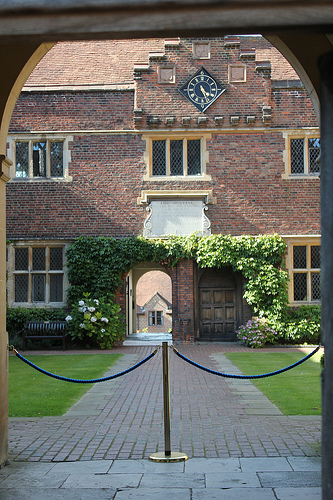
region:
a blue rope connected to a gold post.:
[8, 341, 169, 383]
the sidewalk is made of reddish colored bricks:
[193, 405, 290, 453]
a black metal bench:
[20, 321, 67, 351]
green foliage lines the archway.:
[67, 234, 287, 298]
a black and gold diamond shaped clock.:
[177, 64, 226, 110]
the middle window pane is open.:
[8, 135, 75, 183]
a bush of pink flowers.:
[235, 317, 276, 348]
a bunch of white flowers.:
[66, 292, 107, 333]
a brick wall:
[73, 137, 141, 233]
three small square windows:
[155, 41, 248, 83]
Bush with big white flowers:
[66, 290, 126, 352]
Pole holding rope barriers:
[148, 340, 186, 462]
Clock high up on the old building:
[174, 67, 228, 108]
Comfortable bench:
[21, 318, 69, 349]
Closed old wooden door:
[193, 258, 241, 343]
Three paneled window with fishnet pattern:
[142, 130, 207, 178]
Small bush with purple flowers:
[232, 318, 276, 347]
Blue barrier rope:
[170, 344, 322, 379]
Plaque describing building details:
[146, 199, 207, 238]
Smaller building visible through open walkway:
[133, 276, 172, 342]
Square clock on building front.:
[175, 64, 225, 116]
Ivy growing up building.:
[68, 235, 287, 302]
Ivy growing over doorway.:
[113, 239, 180, 267]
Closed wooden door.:
[195, 259, 243, 342]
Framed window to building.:
[285, 238, 323, 306]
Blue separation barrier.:
[9, 338, 319, 461]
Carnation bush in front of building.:
[66, 297, 117, 343]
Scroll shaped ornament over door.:
[151, 200, 204, 237]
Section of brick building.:
[80, 142, 136, 225]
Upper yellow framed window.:
[138, 135, 210, 182]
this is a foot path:
[113, 393, 153, 432]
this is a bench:
[23, 324, 66, 346]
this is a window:
[149, 135, 202, 173]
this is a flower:
[71, 304, 118, 345]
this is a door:
[125, 280, 173, 342]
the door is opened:
[124, 279, 170, 336]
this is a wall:
[59, 186, 131, 228]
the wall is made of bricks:
[75, 178, 123, 221]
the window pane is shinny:
[51, 144, 60, 171]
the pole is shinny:
[160, 345, 170, 460]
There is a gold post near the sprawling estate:
[159, 332, 170, 466]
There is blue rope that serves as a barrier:
[222, 359, 280, 395]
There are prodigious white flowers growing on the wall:
[74, 299, 102, 353]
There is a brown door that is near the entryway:
[195, 262, 244, 363]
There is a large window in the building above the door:
[142, 136, 227, 192]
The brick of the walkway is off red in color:
[214, 411, 243, 450]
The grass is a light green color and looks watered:
[63, 356, 82, 375]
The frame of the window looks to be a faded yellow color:
[280, 250, 301, 306]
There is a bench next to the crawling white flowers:
[18, 316, 75, 351]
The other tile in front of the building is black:
[254, 465, 290, 495]